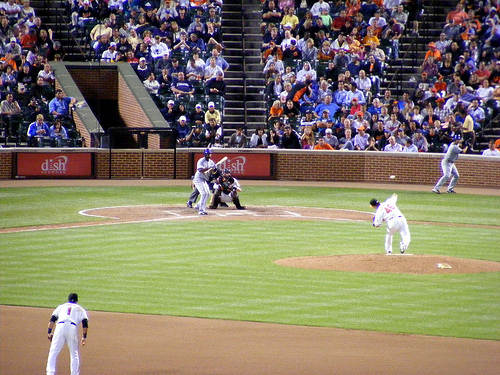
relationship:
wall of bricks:
[6, 138, 499, 182] [95, 144, 111, 176]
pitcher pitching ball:
[353, 182, 424, 261] [378, 171, 403, 186]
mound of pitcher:
[380, 247, 417, 267] [353, 182, 424, 261]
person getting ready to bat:
[193, 141, 218, 216] [206, 153, 234, 179]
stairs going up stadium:
[217, 7, 270, 152] [6, 6, 492, 183]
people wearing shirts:
[27, 112, 66, 143] [28, 119, 51, 144]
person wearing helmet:
[193, 141, 218, 216] [199, 145, 216, 157]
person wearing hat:
[353, 182, 424, 261] [368, 196, 384, 209]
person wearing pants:
[353, 182, 424, 261] [380, 214, 416, 253]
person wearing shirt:
[353, 182, 424, 261] [367, 194, 404, 221]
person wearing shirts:
[353, 182, 424, 261] [28, 119, 51, 144]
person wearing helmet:
[177, 141, 236, 223] [199, 145, 216, 157]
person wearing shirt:
[423, 118, 463, 198] [438, 142, 466, 168]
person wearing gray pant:
[423, 118, 463, 198] [421, 157, 464, 196]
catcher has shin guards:
[211, 167, 253, 217] [209, 186, 232, 211]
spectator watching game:
[6, 6, 492, 183] [3, 8, 493, 374]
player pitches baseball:
[353, 182, 424, 261] [378, 171, 403, 186]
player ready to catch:
[211, 167, 253, 217] [207, 160, 259, 200]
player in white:
[44, 278, 117, 374] [37, 297, 100, 368]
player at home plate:
[177, 141, 236, 223] [202, 202, 262, 221]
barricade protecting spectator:
[6, 138, 499, 182] [6, 6, 492, 183]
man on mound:
[353, 182, 424, 261] [380, 247, 417, 267]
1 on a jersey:
[61, 305, 76, 317] [52, 307, 91, 330]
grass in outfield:
[150, 240, 267, 315] [45, 230, 473, 321]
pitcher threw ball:
[353, 182, 424, 261] [378, 171, 403, 186]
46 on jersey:
[376, 196, 400, 218] [367, 194, 404, 221]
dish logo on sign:
[35, 153, 86, 173] [13, 145, 97, 177]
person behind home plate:
[193, 141, 218, 216] [202, 202, 262, 221]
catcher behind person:
[211, 167, 253, 217] [193, 141, 218, 216]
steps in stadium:
[217, 7, 270, 152] [6, 6, 492, 183]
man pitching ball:
[353, 182, 424, 261] [378, 171, 403, 186]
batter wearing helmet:
[177, 141, 236, 223] [199, 145, 216, 157]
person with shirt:
[177, 141, 236, 223] [367, 194, 404, 221]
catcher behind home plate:
[211, 167, 253, 217] [202, 202, 262, 221]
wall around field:
[6, 138, 499, 182] [2, 176, 497, 367]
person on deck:
[193, 141, 218, 216] [160, 142, 271, 245]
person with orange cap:
[423, 39, 443, 61] [427, 38, 436, 53]